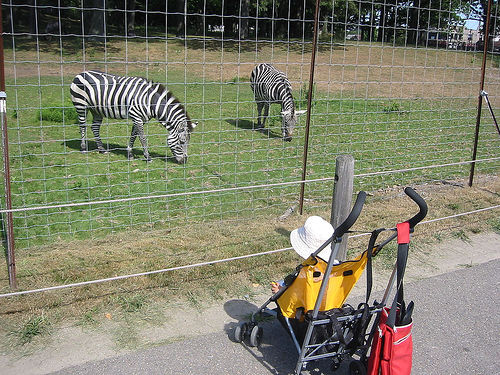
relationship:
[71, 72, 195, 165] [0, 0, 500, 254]
zebra inside a fence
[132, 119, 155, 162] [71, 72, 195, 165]
leg of zebra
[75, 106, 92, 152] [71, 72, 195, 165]
leg of zebra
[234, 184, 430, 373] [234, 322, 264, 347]
stroller has wheel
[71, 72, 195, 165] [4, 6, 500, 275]
zebra behind a fence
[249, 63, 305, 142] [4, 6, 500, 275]
zebra behind a fence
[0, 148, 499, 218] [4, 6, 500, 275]
rope in front of fence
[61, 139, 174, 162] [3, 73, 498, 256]
shadow on grass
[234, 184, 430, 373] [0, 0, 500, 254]
stroller in front of fence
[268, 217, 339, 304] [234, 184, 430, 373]
child in stroller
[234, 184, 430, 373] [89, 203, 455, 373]
stroller in forefront